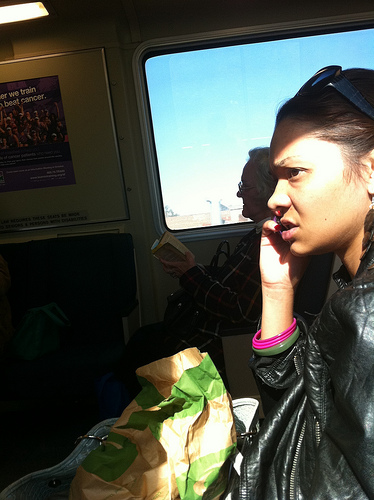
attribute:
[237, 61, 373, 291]
woman — upset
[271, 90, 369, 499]
lady — concerned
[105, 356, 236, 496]
bag — green, tan